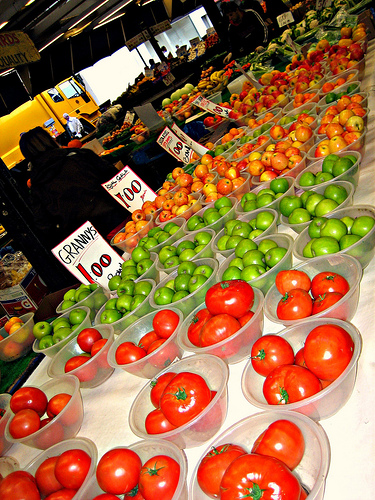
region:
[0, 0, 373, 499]
Produce market.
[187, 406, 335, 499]
Several tomatoes in a clear basket.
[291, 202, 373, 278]
Clear bowl of Granny Smith Apples.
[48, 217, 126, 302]
Grannys. 1.00 per pound.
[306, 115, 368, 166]
Clear bowl of apples.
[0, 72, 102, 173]
Yellow delivery truck.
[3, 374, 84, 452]
Clear bowl of red tomatoes.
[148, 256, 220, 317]
Clear bowl of Granny Smith Apples.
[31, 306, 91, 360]
Clear bowl of Granny Smith Apples.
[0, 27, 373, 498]
Long white table featuring tomatoes, apples, and other produce.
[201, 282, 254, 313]
this is a tomato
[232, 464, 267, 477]
the tomato is red in color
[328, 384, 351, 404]
this is a container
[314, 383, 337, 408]
the container is made of plastic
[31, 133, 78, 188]
this is a lady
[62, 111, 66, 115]
this is a cap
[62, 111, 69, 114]
the cap is white in color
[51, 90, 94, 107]
this is a lorry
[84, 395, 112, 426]
this is a table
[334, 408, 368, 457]
the table is white in color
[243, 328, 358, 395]
Bowl of tomatoes that are for sale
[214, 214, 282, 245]
Bowl of green apples that are for sale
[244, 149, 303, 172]
Bowl of red and yellow apples that are for sale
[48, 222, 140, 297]
Assigned to sell Granny Smiths apples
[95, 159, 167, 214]
Sign to sell yellow and red apples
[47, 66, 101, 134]
Cab of produce truck sitting in the background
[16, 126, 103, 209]
Customer shopping for produce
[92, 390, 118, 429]
Table cloth covering table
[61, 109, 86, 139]
Truck driver exiting truck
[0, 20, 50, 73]
Sign hanging from the ceiling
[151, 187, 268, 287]
green apples in bowls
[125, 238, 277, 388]
red and green fruit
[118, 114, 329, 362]
many different bowls of fruit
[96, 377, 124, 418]
white table under the bowls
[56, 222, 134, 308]
red, black and white sign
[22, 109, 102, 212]
person behind the fruit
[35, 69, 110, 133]
green truck behind the people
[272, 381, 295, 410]
green part of the tomato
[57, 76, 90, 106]
window on the truck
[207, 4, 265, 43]
man looking for fruit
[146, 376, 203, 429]
Red tomatoes in plate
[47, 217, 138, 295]
Grannys 1.00 sign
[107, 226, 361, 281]
Bunches of green apples in clear bowls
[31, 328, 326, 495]
Bunches of red apples in clear bowls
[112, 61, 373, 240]
Bunches of red and yellow apples in clear bowls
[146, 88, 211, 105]
Green melons on background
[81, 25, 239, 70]
Market place windows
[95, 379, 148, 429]
White table with fruits on it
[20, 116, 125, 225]
Shopper in the darkness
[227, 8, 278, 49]
Person in black and white track suit